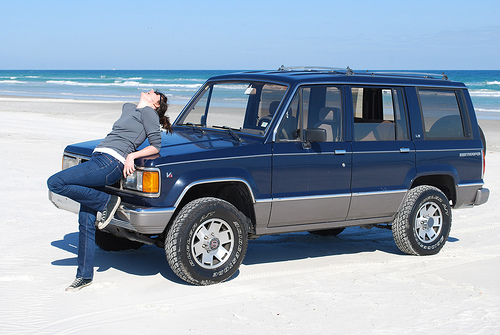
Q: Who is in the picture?
A: A young woman.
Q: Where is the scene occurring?
A: On the Beach.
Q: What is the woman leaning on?
A: A SUV.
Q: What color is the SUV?
A: Blue.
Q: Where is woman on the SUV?
A: Leaning on hood and bumper.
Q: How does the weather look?
A: Perfect, sunny and clear.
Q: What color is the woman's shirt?
A: Grey.